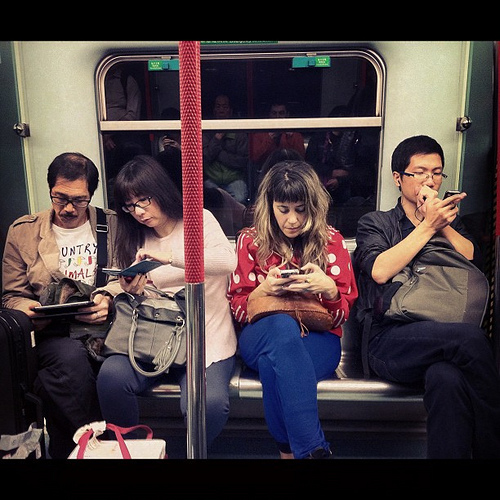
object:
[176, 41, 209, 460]
pole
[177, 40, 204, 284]
grip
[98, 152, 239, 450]
passengers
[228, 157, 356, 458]
passengers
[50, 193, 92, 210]
eyeglasses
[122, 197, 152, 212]
eyeglasses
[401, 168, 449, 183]
eyeglasses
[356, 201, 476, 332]
black jacket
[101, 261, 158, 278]
book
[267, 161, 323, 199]
hair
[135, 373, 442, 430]
seat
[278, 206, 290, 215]
eye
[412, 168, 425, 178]
eye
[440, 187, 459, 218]
phone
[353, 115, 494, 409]
asian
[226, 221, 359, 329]
shirt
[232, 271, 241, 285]
dots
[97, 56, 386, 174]
window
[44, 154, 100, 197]
hair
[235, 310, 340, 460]
pants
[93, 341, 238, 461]
pants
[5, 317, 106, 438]
pants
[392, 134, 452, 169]
hair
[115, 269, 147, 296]
hand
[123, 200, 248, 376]
sweater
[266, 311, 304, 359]
lap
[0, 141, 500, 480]
people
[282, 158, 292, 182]
parted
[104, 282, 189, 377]
handbag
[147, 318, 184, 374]
tassels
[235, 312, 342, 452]
jeans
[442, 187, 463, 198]
cellphone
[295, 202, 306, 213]
eye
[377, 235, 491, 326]
bag-lap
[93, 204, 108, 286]
strap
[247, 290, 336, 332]
bag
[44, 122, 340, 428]
woman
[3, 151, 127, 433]
man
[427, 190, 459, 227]
hand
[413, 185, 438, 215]
hand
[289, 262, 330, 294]
hand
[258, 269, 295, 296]
hand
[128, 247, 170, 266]
hand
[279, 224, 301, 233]
mouth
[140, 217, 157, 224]
mouth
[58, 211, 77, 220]
mouth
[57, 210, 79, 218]
mustache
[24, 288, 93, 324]
tablet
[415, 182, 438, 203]
mouth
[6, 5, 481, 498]
train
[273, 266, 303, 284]
phone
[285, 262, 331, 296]
hands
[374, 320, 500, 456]
jeans